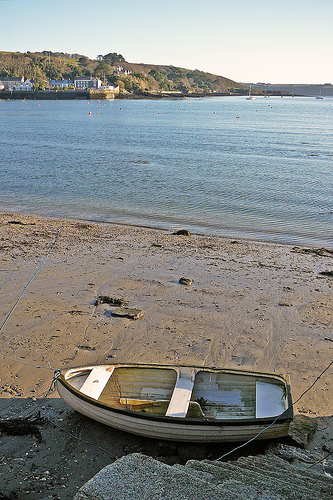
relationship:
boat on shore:
[52, 362, 296, 445] [0, 210, 333, 446]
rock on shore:
[109, 304, 144, 320] [0, 210, 333, 446]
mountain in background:
[0, 51, 236, 89] [1, 1, 333, 107]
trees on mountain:
[40, 61, 65, 79] [0, 51, 236, 89]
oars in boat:
[121, 395, 204, 414] [52, 362, 296, 445]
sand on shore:
[0, 210, 332, 468] [0, 210, 333, 446]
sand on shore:
[39, 265, 93, 301] [0, 210, 333, 446]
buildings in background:
[1, 73, 123, 95] [1, 1, 333, 107]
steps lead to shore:
[69, 447, 333, 500] [0, 210, 333, 446]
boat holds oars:
[52, 362, 296, 445] [121, 395, 204, 414]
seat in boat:
[159, 373, 201, 417] [52, 362, 296, 445]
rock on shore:
[179, 274, 198, 287] [0, 210, 333, 446]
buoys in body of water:
[7, 97, 331, 122] [1, 98, 333, 236]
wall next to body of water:
[2, 90, 115, 101] [1, 98, 333, 236]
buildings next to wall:
[1, 73, 123, 95] [2, 90, 115, 101]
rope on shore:
[3, 224, 65, 340] [0, 210, 333, 446]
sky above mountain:
[1, 1, 330, 54] [0, 51, 236, 89]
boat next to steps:
[52, 362, 296, 445] [69, 447, 333, 500]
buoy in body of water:
[87, 108, 94, 118] [1, 98, 333, 236]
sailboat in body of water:
[244, 86, 262, 102] [1, 98, 333, 236]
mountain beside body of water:
[0, 51, 236, 89] [1, 98, 333, 236]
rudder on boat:
[189, 396, 221, 424] [52, 362, 296, 445]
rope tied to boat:
[10, 368, 64, 421] [52, 362, 296, 445]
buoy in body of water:
[210, 107, 221, 119] [1, 98, 333, 236]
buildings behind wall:
[1, 73, 123, 95] [2, 90, 115, 101]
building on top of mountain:
[96, 54, 106, 64] [0, 51, 236, 89]